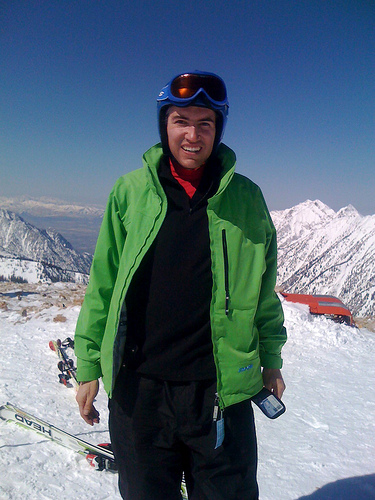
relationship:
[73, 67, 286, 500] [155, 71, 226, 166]
man wears goggles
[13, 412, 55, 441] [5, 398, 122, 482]
writing on ski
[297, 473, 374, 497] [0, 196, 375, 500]
shadow in snow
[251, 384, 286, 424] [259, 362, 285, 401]
phone in hand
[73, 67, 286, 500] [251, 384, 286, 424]
man has phone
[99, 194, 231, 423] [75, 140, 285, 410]
zipper on green jacket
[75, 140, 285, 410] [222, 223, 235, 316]
green jacket has zipper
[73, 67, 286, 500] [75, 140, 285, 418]
man wears green jacket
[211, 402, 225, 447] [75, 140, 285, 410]
tag on green jacket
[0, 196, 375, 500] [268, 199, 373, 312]
snow on mountains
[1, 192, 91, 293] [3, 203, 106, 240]
mountain on distance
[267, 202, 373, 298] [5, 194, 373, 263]
mountain on distance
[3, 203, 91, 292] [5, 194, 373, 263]
mountain on distance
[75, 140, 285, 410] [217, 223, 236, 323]
green jacket has zippers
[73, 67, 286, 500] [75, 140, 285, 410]
man wears green jacket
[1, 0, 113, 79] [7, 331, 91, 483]
skis on snow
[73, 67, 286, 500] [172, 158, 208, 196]
man wearing shirt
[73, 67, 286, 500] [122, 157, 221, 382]
man wearing shirt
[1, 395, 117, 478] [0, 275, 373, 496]
ski on ground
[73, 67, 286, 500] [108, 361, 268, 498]
man wearing pants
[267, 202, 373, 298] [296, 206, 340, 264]
mountain covered in ice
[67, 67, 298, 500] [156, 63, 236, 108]
man wearing goggles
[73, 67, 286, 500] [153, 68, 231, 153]
man wearing helmet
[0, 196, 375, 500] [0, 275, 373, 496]
snow on ground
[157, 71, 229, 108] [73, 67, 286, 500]
glasses on man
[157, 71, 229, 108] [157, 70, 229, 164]
glasses on head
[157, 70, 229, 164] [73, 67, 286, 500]
head on man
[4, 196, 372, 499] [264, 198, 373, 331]
snow on mountain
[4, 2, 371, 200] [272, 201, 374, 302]
sky above mountains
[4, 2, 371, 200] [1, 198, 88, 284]
sky above mountains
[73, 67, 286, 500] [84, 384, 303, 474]
man wearing pants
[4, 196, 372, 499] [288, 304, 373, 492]
snow on ground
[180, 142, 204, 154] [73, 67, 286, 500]
smile on man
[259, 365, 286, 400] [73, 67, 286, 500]
hand of man